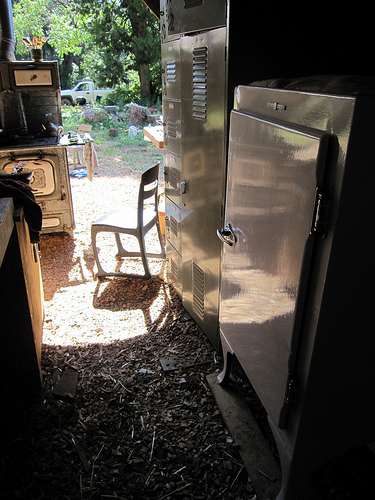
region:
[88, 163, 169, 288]
mono bloc chair under sunlight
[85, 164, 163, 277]
Single chair beaming sun light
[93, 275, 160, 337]
Shadow of a chair on the ground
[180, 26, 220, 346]
Tall metal brown locker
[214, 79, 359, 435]
Silver antique style refrigerator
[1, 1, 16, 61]
Part of an old stove pipe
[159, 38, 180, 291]
Metal locker style cabinets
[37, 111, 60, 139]
Old style coffee pot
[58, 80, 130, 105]
White pickup truck partially hidden by a bush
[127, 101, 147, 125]
Tree stump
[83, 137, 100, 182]
Yellow and grey striped cloth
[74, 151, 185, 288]
Chair in the sun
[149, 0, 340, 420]
Large shiny silver containers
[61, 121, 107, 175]
Wooden table with table cloth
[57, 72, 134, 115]
White truck behind the tree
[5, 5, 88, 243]
Tall grey and white stove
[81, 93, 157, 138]
Tree trunks in the grass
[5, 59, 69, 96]
White drawer above the stove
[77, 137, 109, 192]
Table cloth is striped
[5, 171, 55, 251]
Brown towel hanging off of cabinet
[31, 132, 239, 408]
The stove and cabinets are on dirt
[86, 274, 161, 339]
chair shadow visible on ground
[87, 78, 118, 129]
tree lying in the grass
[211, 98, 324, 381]
metal refrigerator/freezer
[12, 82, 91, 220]
wood cooking stove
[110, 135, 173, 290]
chair next to the stove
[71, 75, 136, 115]
white truck in the yard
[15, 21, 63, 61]
utensils on top of wood stove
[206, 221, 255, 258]
handle on the refrigerator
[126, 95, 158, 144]
tree stump in the yard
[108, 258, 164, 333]
chair shadow on the ground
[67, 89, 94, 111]
grill in the yard